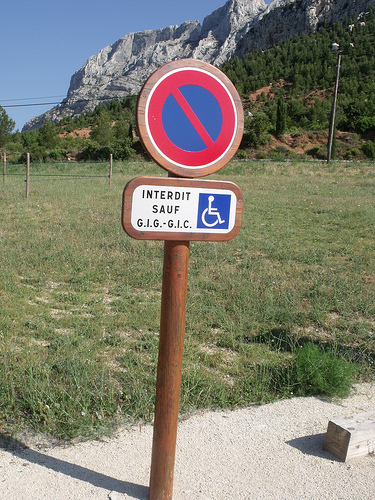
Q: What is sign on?
A: Pole.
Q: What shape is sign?
A: Round.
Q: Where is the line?
A: On circle.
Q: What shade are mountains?
A: Gray.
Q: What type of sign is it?
A: Handicapped parking only.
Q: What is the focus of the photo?
A: Handicap sign in front of mountains.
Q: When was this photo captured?
A: Daytime.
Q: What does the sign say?
A: Handicap parking.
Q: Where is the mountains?
A: Background.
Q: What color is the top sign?
A: Red and blue.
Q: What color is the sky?
A: Blue.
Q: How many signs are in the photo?
A: 1.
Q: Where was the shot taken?
A: At the park.